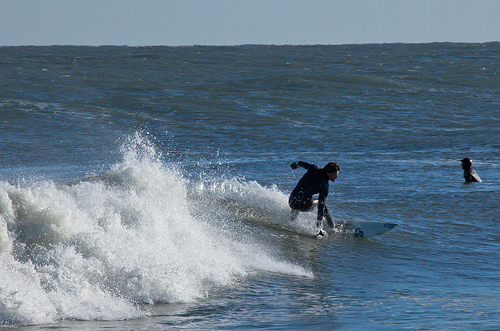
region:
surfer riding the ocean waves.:
[280, 153, 400, 244]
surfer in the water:
[261, 149, 380, 251]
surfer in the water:
[284, 149, 344, 243]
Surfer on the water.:
[280, 143, 400, 238]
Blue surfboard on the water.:
[322, 214, 400, 246]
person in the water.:
[452, 149, 484, 186]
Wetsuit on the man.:
[282, 150, 351, 240]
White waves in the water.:
[4, 128, 330, 327]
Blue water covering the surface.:
[2, 45, 498, 330]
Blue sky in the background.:
[2, 0, 497, 43]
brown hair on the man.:
[316, 153, 344, 185]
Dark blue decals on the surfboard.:
[346, 217, 401, 242]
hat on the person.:
[455, 153, 475, 170]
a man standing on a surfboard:
[281, 155, 342, 235]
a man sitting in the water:
[457, 154, 482, 181]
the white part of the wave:
[3, 169, 291, 306]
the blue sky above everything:
[2, 2, 499, 44]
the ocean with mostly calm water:
[1, 48, 492, 329]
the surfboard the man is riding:
[334, 214, 399, 239]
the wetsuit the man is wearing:
[289, 160, 328, 218]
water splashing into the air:
[106, 114, 235, 174]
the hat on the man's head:
[454, 153, 472, 167]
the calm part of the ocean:
[12, 51, 497, 151]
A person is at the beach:
[15, 32, 455, 315]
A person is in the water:
[18, 72, 421, 327]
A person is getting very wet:
[33, 60, 415, 328]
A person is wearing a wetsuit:
[25, 38, 417, 318]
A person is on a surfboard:
[40, 41, 420, 326]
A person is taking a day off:
[26, 56, 431, 321]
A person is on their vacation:
[60, 83, 422, 309]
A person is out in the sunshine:
[11, 80, 426, 301]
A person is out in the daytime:
[60, 82, 430, 304]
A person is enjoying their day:
[47, 83, 443, 327]